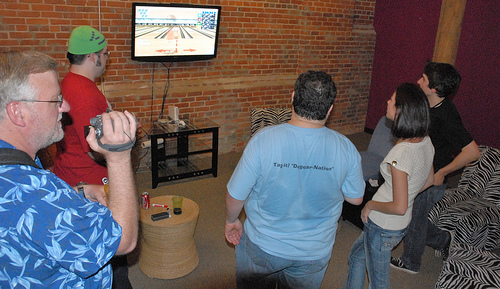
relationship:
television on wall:
[130, 1, 222, 59] [3, 1, 375, 171]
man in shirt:
[223, 70, 364, 287] [241, 123, 364, 255]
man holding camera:
[1, 49, 161, 287] [79, 103, 141, 153]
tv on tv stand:
[129, 3, 222, 63] [138, 117, 218, 188]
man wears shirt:
[36, 22, 135, 287] [38, 70, 113, 183]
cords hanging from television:
[149, 61, 174, 119] [133, 4, 219, 59]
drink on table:
[169, 195, 184, 214] [139, 193, 200, 280]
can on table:
[140, 188, 152, 209] [139, 193, 200, 280]